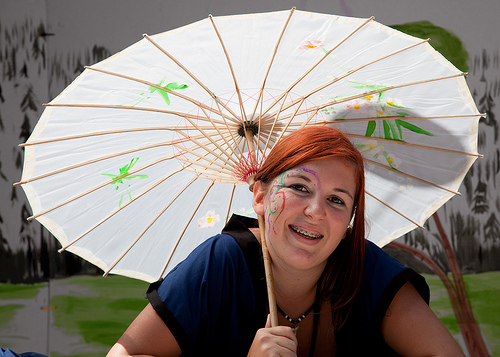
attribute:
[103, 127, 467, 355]
girl — smiling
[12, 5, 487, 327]
umbrella — white, green, transparent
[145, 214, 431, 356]
shirt — blue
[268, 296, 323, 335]
necklace — black, dark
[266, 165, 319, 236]
paint — colorful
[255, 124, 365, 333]
hair — red, brown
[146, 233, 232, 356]
sleeve — short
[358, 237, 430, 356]
sleeve — short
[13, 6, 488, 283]
frame — wooden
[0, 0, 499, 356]
wall — painted, white, grey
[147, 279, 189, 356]
border — black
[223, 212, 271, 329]
border — black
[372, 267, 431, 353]
border — black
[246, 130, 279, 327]
stick — wooden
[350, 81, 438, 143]
flowers — white, painted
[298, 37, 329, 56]
flowers — white, painted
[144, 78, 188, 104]
flowers — green, painted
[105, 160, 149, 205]
flowers — green, painted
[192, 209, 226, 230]
flowers — white, painted